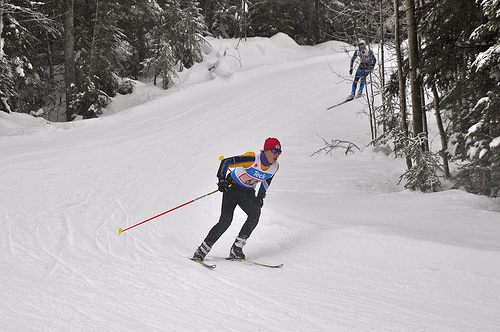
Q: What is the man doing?
A: Skiing.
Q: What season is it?
A: Winter.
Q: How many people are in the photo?
A: Two.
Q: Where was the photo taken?
A: On a mountain.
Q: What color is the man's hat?
A: Red.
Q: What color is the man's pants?
A: Black.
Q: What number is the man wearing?
A: 62.